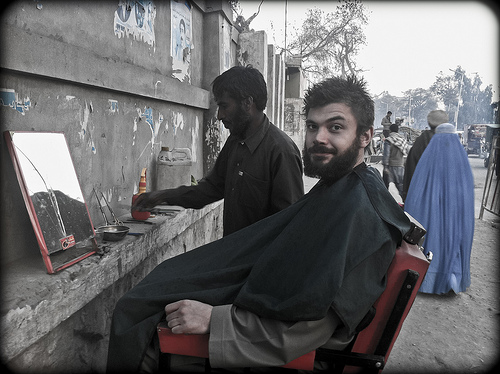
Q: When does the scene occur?
A: Daytime.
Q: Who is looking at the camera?
A: The man in the chair.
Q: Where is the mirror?
A: In front of the man in the chair.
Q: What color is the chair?
A: Red.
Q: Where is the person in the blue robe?
A: To the right.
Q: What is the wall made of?
A: Concrete.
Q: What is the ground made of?
A: Dirt.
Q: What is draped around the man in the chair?
A: A black cape.